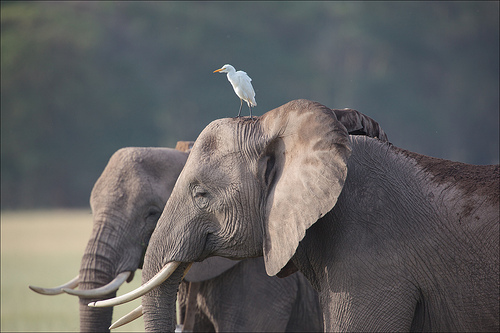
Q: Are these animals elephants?
A: Yes, all the animals are elephants.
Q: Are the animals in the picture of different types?
A: No, all the animals are elephants.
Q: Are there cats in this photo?
A: No, there are no cats.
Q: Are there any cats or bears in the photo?
A: No, there are no cats or bears.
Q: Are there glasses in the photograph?
A: No, there are no glasses.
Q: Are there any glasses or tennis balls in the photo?
A: No, there are no glasses or tennis balls.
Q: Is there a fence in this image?
A: No, there are no fences.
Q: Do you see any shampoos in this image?
A: No, there are no shampoos.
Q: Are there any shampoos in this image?
A: No, there are no shampoos.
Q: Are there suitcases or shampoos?
A: No, there are no shampoos or suitcases.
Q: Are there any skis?
A: No, there are no skis.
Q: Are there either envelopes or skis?
A: No, there are no skis or envelopes.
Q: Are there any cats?
A: No, there are no cats.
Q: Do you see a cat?
A: No, there are no cats.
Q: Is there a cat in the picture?
A: No, there are no cats.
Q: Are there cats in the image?
A: No, there are no cats.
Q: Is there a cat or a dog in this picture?
A: No, there are no cats or dogs.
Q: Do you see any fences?
A: No, there are no fences.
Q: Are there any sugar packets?
A: No, there are no sugar packets.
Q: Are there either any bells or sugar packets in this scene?
A: No, there are no sugar packets or bells.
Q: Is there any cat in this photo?
A: No, there are no cats.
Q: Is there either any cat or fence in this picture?
A: No, there are no cats or fences.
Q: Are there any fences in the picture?
A: No, there are no fences.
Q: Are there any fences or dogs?
A: No, there are no fences or dogs.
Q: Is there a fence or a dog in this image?
A: No, there are no fences or dogs.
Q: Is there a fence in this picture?
A: No, there are no fences.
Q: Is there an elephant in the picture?
A: Yes, there is an elephant.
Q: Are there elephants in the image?
A: Yes, there is an elephant.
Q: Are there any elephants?
A: Yes, there is an elephant.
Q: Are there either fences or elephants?
A: Yes, there is an elephant.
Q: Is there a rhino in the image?
A: No, there are no rhinos.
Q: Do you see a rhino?
A: No, there are no rhinos.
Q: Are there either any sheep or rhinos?
A: No, there are no rhinos or sheep.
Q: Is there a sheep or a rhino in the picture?
A: No, there are no rhinos or sheep.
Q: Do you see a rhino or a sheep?
A: No, there are no rhinos or sheep.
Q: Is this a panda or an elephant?
A: This is an elephant.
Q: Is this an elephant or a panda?
A: This is an elephant.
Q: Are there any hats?
A: Yes, there is a hat.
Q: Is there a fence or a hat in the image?
A: Yes, there is a hat.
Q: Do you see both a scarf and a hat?
A: No, there is a hat but no scarves.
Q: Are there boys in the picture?
A: No, there are no boys.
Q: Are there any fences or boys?
A: No, there are no boys or fences.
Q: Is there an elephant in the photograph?
A: Yes, there is an elephant.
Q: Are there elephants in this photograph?
A: Yes, there is an elephant.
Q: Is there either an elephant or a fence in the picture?
A: Yes, there is an elephant.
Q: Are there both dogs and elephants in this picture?
A: No, there is an elephant but no dogs.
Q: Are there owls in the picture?
A: No, there are no owls.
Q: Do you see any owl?
A: No, there are no owls.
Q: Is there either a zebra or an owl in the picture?
A: No, there are no owls or zebras.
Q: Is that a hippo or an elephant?
A: That is an elephant.